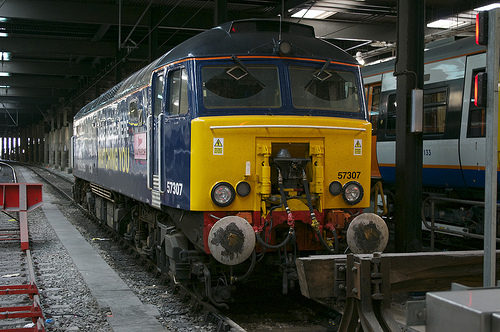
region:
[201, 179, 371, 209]
headlights on train engine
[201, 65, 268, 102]
clean area on dusty train windshield made by wipers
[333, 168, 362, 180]
number on train #57307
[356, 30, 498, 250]
white blue and yellow train next to blue and yellow train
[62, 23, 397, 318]
engine car of blue and yellow train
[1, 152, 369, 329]
two sets of train tracks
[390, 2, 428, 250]
dark colored metal support beam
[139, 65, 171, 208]
train's engine car door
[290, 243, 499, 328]
wood and metal train parking barrier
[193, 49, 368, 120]
train's engine car windshield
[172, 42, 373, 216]
a train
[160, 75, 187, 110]
window on the bus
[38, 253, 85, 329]
small rocks on the ground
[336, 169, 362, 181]
numbers on the train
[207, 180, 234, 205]
the headlight on the train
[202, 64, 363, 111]
windshield on the train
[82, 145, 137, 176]
the writing on the train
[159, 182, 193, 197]
numbers on the side of the train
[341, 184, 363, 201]
a clear headlight on the train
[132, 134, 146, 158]
a sign on the train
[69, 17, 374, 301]
yellow and blue train engine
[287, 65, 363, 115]
dirty window with clean spot where wipers wiped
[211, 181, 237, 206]
train headlight with black border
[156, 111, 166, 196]
metal handle next to door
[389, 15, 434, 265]
a dark colored post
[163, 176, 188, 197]
number in white on front side of train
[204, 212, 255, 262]
a round metal bumper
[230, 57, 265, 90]
a train's windshield wiper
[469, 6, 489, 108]
pair of red lights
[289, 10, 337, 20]
light in ceiling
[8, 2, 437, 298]
a passeger train for commuters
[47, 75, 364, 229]
a blue and yellow train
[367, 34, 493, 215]
a white, blue and red train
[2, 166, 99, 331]
this train track is blocked off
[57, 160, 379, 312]
this train is being repaired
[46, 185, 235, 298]
this train must be fixed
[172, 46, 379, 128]
this train is old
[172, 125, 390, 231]
the lights are on the yellow part of the train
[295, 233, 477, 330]
a block on the tracks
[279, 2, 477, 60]
lights in the area